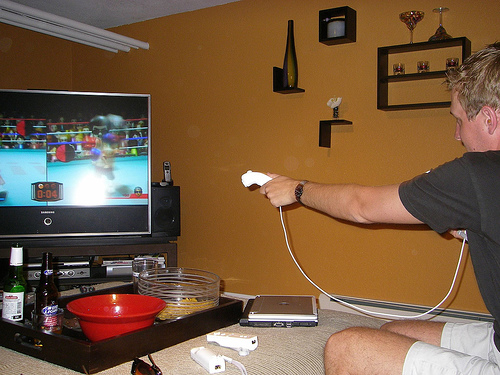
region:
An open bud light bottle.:
[36, 250, 61, 329]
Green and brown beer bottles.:
[1, 243, 61, 331]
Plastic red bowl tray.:
[66, 294, 169, 344]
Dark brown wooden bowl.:
[3, 271, 243, 372]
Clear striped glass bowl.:
[138, 267, 224, 321]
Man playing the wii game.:
[240, 44, 498, 374]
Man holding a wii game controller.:
[237, 157, 307, 217]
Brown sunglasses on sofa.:
[123, 353, 164, 373]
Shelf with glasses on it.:
[367, 6, 469, 111]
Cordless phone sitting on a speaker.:
[157, 157, 177, 187]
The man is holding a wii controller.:
[196, 150, 328, 224]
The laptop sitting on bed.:
[169, 252, 329, 335]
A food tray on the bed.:
[17, 283, 242, 360]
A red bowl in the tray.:
[67, 278, 166, 330]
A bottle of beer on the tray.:
[26, 247, 59, 329]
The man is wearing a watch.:
[278, 171, 318, 216]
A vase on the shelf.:
[268, 8, 314, 104]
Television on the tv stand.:
[11, 81, 161, 249]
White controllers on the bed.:
[184, 320, 265, 367]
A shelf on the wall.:
[366, 38, 482, 138]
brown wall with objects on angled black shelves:
[147, 6, 493, 311]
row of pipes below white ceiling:
[1, 2, 211, 53]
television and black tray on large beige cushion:
[0, 90, 380, 370]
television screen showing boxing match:
[5, 86, 150, 236]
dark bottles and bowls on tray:
[5, 245, 240, 355]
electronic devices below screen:
[0, 237, 170, 279]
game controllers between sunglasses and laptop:
[132, 290, 327, 370]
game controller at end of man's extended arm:
[235, 165, 410, 230]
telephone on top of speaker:
[152, 151, 182, 241]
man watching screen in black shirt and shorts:
[395, 45, 495, 370]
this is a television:
[86, 171, 137, 212]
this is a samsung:
[75, 190, 140, 327]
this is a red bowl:
[56, 271, 131, 335]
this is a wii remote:
[222, 208, 318, 267]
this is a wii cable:
[292, 228, 351, 284]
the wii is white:
[169, 333, 211, 373]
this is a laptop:
[270, 297, 301, 353]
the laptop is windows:
[261, 297, 301, 322]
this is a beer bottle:
[39, 279, 66, 316]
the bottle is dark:
[28, 288, 68, 315]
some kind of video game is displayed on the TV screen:
[1, 83, 156, 239]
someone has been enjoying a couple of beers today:
[3, 240, 62, 337]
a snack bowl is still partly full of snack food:
[134, 264, 221, 326]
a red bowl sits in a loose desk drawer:
[62, 290, 171, 342]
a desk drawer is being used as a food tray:
[3, 272, 246, 372]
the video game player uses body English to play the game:
[237, 42, 499, 324]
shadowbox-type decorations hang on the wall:
[266, 1, 473, 151]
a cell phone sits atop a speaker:
[157, 158, 176, 187]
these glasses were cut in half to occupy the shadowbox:
[396, 3, 454, 43]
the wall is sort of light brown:
[158, 1, 489, 308]